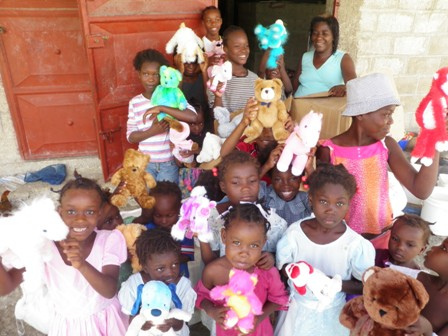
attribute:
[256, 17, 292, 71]
stuffed animal — blue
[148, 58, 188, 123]
bear — blue-green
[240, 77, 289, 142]
teddybear — light brown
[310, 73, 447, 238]
girl — little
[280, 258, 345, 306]
dog — red and white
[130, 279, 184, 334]
dog — blue and white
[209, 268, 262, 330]
bear — multicolored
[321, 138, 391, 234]
shirt — pink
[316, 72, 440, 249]
girl — little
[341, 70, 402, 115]
hat — beige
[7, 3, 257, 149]
door — red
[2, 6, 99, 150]
door — orange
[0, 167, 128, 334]
girl — young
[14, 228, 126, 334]
dress — pink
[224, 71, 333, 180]
toys — stuffed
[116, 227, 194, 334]
girl — small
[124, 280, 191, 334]
stuffed dog — blue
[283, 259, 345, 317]
stuffed dog — white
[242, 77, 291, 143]
teddy bear — brown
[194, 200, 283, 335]
girl — yellow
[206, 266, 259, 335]
bear — pink, stuffed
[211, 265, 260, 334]
stuffed animal — pink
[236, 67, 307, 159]
toy — monkey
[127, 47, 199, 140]
girl — yellow, green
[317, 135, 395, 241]
dress — dark pink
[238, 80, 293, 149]
teddy bear — brown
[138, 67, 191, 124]
animal — green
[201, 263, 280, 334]
stuffed animal — pink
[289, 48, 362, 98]
tank — light blue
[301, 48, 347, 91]
tank top — blue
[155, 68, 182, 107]
bear — blue